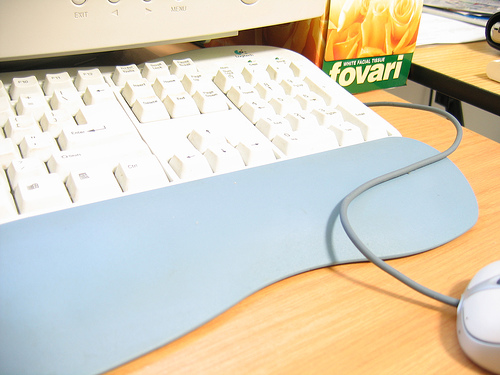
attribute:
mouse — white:
[458, 261, 500, 373]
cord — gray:
[339, 101, 463, 306]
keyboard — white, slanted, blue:
[3, 43, 404, 227]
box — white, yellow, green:
[205, 2, 425, 96]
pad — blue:
[1, 136, 481, 374]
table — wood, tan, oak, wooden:
[98, 43, 498, 373]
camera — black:
[486, 7, 500, 85]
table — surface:
[408, 39, 499, 117]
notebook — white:
[422, 1, 500, 26]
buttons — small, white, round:
[71, 0, 261, 8]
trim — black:
[408, 59, 500, 120]